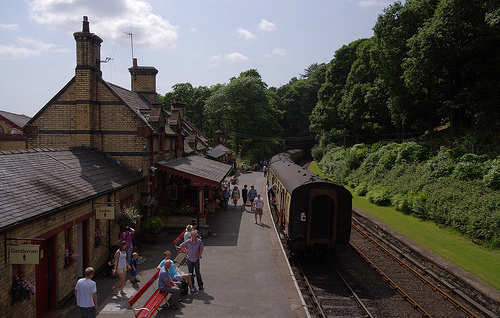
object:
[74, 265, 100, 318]
man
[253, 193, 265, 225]
man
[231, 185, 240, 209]
people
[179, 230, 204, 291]
man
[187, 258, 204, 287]
blue jeans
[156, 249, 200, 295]
person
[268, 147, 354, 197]
top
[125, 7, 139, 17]
clouds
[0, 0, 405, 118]
sky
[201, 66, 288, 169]
tree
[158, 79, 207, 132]
tree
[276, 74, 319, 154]
tree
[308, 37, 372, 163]
tree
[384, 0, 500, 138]
tree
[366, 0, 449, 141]
trees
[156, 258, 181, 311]
man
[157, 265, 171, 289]
top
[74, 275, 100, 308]
white shirt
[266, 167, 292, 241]
right side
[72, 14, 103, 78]
chimney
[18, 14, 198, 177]
building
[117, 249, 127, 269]
tank top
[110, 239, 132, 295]
woman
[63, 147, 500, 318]
ground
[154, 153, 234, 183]
covering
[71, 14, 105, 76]
tower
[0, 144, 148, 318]
building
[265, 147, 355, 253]
train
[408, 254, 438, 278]
tracks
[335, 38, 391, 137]
trees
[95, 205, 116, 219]
sign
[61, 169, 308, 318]
platform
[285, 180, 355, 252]
back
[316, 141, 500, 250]
bushes line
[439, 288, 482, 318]
tracks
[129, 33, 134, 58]
flagpole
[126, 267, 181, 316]
bench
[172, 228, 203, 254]
bench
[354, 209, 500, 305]
track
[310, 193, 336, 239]
door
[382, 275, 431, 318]
tracks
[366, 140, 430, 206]
bushes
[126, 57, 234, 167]
building